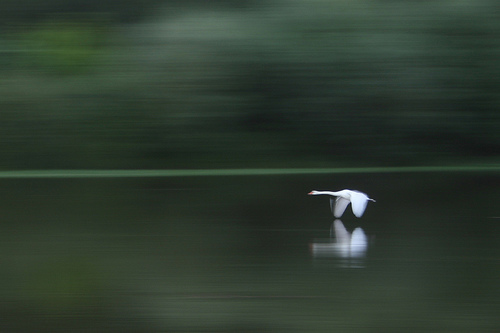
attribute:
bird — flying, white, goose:
[304, 179, 384, 235]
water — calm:
[0, 2, 499, 333]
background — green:
[3, 8, 500, 89]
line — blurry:
[0, 161, 499, 181]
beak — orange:
[305, 188, 312, 199]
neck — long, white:
[317, 186, 338, 199]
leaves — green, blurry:
[15, 15, 113, 82]